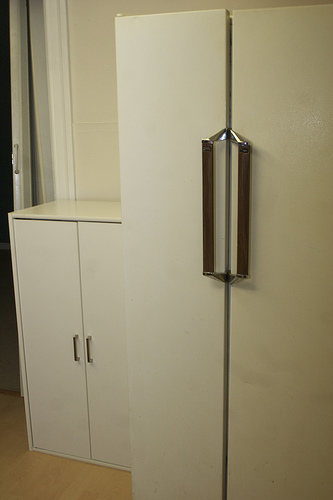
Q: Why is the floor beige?
A: Wooden.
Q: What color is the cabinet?
A: Cream.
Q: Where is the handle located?
A: Middle of door.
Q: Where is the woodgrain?
A: On the handle.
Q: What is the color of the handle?
A: Brown.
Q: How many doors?
A: 2.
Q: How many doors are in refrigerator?
A: 2.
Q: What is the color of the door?
A: Grey.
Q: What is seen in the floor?
A: Light reflection.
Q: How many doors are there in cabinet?
A: 2.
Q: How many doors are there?
A: 2.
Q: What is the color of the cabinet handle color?
A: Grey.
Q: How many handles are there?
A: 2.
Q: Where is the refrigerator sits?
A: Wooden floor.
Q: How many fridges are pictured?
A: One.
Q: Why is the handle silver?
A: Design.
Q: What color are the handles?
A: Brown.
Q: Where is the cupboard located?
A: On floor.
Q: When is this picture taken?
A: Daytime.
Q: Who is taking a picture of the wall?
A: Owner.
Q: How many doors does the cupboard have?
A: Two.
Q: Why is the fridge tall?
A: Design.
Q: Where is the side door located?
A: Left of picture.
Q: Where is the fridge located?
A: Kitchen area.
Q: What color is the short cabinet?
A: White.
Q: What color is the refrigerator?
A: White.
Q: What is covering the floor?
A: Wood.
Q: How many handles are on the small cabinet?
A: 2.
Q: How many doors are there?
A: 4.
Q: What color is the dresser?
A: White.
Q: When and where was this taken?
A: At night in someone's house.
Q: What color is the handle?
A: Brown.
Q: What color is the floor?
A: Yellow.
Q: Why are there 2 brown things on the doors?
A: To open them.